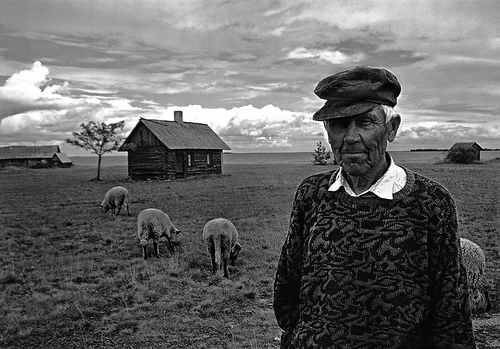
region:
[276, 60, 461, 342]
this is a man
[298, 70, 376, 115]
this is a cap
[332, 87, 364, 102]
the cap is black in color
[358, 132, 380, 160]
the man is light skinned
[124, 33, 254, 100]
this is the sky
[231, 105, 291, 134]
these are the clouds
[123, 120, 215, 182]
this is a house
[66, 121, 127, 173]
this is a tree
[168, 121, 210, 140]
this is the roof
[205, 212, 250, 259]
this is a sheep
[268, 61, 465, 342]
elderly man in a field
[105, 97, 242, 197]
log cabin in a field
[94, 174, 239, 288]
three graing sheep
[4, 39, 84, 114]
dramatic sky filled with clouds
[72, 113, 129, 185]
tree beside a cabin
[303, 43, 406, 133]
hat on an elderly man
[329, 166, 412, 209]
white collar of a shirt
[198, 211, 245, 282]
sheep grazing in a field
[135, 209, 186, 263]
sheep grazing in a field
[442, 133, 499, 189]
log cabin in the distance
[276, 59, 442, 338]
this is an old man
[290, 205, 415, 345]
he is wearing sweater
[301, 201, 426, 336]
the sweater is black in color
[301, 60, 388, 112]
he is wearing a cap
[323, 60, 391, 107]
the cap is old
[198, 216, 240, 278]
this is a sheep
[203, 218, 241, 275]
the sheep is feeding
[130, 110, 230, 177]
this is a house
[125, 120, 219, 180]
the house is small in size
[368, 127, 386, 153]
the face has wrinkles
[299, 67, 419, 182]
head of a man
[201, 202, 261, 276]
animal on the field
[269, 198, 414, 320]
sweater on the man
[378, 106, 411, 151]
ear of the man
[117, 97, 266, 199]
house in the background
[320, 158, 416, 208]
collar of the shirt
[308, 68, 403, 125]
hat on man's head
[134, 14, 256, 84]
clouds in the sky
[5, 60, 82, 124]
clouds in the distance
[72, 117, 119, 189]
tree next to the house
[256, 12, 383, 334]
ELDERLY MAN IN FIELD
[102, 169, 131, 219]
FURRY SHEEP IN FIELD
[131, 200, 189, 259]
FURRY SHEEP IN FIELD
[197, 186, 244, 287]
FURRY SHEEP IN FIELD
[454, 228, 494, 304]
FURRY SHEEP IN FIELD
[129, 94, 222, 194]
SMALL WOODEN BUILDING IN BACKROOM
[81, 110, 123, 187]
SMALL TREE NEAR BUILDING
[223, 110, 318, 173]
WHITE CLOUD IN BACKGROUND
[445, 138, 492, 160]
SMALL HUT ON RIGHT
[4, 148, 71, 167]
BARN IN BACKGROUND